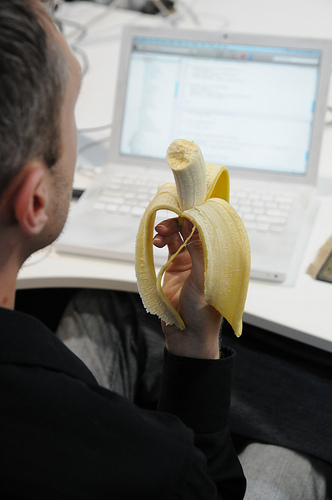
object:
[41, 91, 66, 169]
sideburn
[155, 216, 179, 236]
finger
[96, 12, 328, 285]
computer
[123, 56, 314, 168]
screen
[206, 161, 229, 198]
banana peel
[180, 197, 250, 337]
banana peel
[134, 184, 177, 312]
banana peel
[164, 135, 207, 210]
banana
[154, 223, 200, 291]
string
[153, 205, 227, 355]
hand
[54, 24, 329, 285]
laptop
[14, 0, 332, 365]
desk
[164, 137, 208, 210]
fruit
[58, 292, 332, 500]
crossed legs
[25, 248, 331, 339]
table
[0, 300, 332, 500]
suit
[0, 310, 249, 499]
black jacket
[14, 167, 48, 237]
ear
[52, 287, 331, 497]
jeans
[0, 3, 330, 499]
gentleman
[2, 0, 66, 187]
hair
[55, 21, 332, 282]
computer